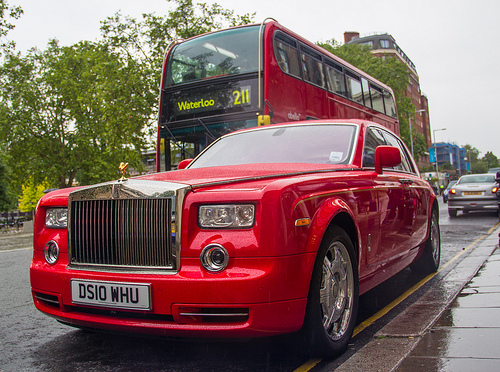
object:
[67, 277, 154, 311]
plate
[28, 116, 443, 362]
car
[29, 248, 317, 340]
bumper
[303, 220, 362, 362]
wheel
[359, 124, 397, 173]
side window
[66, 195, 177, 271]
grill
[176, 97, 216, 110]
green waterloo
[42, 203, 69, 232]
light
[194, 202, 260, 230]
light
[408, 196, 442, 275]
wheel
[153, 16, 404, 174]
bus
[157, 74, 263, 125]
display